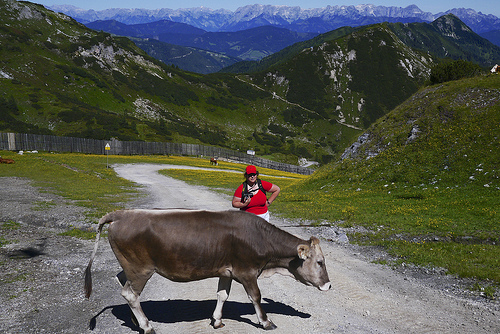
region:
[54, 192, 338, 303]
brown cow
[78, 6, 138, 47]
white clouds in blue sky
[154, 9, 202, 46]
white clouds in blue sky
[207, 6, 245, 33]
white clouds in blue sky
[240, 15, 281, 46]
white clouds in blue sky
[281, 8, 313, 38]
white clouds in blue sky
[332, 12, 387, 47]
white clouds in blue sky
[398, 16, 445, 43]
white clouds in blue sky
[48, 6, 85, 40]
white clouds in blue sky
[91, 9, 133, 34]
white clouds in blue sky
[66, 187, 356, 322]
A cow crossing the road.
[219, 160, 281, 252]
A person waiting for the cow to cross.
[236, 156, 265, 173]
The person is wearing a red cap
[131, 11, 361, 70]
Mountains in the background.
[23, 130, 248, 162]
A fence on the side of the mountains.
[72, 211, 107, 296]
The cow has a long tail.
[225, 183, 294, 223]
Person is wearing a red shirt.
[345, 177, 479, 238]
The grass has yellow flowers.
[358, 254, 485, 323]
Rocks and pebbles on the road.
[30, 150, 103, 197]
The grass is trimmed.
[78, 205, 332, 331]
brown and white cow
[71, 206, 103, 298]
tail of brown cow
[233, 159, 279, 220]
woman standing behind cow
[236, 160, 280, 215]
woman wearing red shirt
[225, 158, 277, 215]
woman wearing a red cap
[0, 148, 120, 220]
green and dirt area besides dirt road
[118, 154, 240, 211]
dirt road between two grass areas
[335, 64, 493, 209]
steep grass hill area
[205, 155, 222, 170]
animal in the background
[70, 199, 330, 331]
cow crossing the dirt path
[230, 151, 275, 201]
woman wearing red hat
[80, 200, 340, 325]
cow near a woman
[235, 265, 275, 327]
leg of a cow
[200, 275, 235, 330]
leg of a cow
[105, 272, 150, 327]
leg of a cow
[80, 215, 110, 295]
tail on a cow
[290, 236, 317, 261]
ear of a cow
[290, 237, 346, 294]
face of a cow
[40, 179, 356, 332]
this is a cow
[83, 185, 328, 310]
the cow is brown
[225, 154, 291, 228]
this is a woman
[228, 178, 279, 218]
woman wearing a red shirt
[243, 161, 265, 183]
woman with red had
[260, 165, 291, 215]
woman has arm on hip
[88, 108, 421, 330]
a curved gravel road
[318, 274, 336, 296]
white nose on cow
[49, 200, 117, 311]
tail of the cow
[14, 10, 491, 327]
a bright and clear day